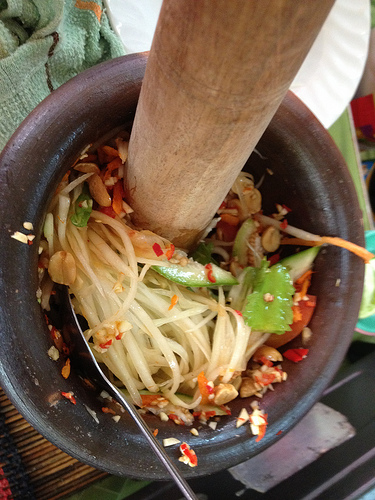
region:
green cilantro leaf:
[242, 263, 292, 334]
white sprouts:
[37, 177, 367, 403]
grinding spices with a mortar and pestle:
[0, 1, 372, 479]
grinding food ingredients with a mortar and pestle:
[2, 0, 363, 480]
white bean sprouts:
[41, 174, 245, 423]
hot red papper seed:
[285, 346, 305, 357]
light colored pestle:
[122, 0, 332, 242]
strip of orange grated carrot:
[196, 369, 205, 399]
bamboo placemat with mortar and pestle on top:
[128, 0, 338, 240]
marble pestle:
[130, 0, 337, 235]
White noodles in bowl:
[58, 222, 235, 400]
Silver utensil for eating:
[43, 283, 200, 493]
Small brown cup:
[6, 52, 348, 494]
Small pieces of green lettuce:
[139, 239, 300, 336]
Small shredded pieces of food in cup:
[51, 155, 291, 465]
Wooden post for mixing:
[151, 0, 344, 245]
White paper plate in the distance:
[101, 3, 371, 131]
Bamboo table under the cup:
[5, 376, 118, 497]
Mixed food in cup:
[55, 137, 309, 408]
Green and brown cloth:
[4, 1, 128, 149]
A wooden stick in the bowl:
[121, 5, 285, 240]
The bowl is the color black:
[38, 395, 311, 471]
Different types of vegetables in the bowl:
[46, 200, 283, 371]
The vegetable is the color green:
[243, 259, 295, 333]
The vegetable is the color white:
[100, 290, 216, 360]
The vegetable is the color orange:
[90, 143, 134, 216]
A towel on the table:
[7, 7, 116, 98]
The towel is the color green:
[7, 7, 101, 109]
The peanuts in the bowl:
[242, 188, 283, 251]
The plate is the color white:
[304, 3, 367, 120]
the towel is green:
[16, 17, 76, 74]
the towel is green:
[2, 66, 55, 114]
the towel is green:
[3, 30, 66, 92]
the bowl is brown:
[8, 90, 338, 496]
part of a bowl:
[261, 427, 273, 437]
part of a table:
[314, 455, 319, 468]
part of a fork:
[171, 470, 182, 489]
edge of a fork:
[149, 441, 163, 451]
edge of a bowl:
[62, 398, 78, 407]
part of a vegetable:
[260, 317, 271, 328]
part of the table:
[309, 423, 320, 444]